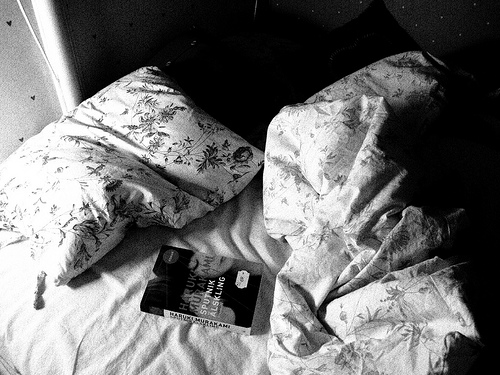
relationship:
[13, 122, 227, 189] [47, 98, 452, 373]
pillow on bed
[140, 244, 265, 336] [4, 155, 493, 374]
book on bed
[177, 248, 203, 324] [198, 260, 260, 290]
part of a book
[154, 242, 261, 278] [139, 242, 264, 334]
woman on book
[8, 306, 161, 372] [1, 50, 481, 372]
sheet on bed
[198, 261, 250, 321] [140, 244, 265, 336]
side of book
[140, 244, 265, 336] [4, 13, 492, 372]
book on bed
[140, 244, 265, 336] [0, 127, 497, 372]
book on bed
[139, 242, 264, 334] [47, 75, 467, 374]
book laying on bed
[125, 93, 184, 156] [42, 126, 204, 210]
design on pillow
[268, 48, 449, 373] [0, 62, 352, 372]
sheet laying on bed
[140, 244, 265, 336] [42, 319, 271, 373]
book laying on sheet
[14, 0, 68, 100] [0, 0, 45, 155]
cord for blind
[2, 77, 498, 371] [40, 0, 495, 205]
bed made on window